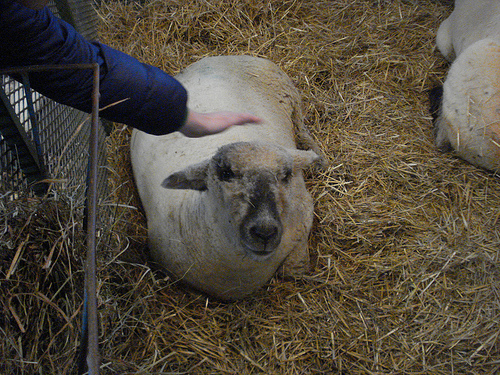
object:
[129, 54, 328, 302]
sheep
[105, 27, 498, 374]
hay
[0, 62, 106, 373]
fence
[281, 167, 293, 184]
eye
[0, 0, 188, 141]
arm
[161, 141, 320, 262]
head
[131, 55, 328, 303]
fur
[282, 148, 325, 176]
ear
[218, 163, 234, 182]
eye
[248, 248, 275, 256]
mouth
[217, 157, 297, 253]
face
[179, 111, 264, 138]
hand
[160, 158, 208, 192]
ear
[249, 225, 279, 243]
nose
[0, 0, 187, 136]
coat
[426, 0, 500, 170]
sheep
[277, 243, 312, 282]
leg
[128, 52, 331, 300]
wool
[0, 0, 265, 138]
person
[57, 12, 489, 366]
bedding